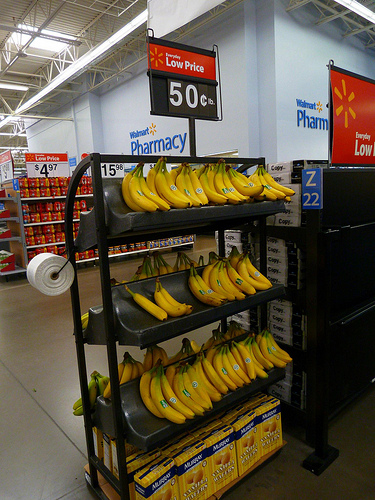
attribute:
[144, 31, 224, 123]
sign — red, black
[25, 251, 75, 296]
bags — plastic, white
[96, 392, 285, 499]
cookies — vanilla wafer 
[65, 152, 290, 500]
shelves — metallic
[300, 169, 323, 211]
sign — blue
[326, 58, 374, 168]
sign — red and white 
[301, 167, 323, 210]
aisle sign — blue 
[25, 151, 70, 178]
sign — red, white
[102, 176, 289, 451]
rack — black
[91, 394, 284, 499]
vanilla wafers — packaged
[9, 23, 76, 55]
skylight — on the roof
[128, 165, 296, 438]
bananas — yellow, in a bundle, ripe, in a bunch